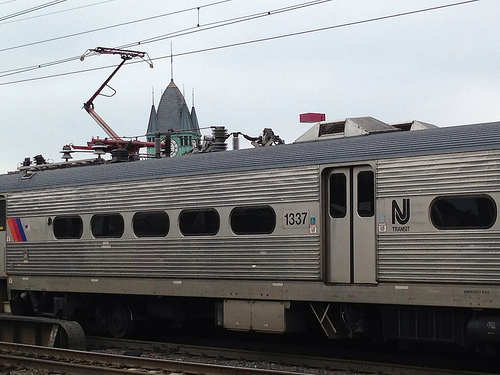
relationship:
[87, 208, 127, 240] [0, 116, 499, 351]
window on train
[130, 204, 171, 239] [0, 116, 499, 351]
window on train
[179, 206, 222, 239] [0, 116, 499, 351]
window on train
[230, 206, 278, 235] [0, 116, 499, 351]
window on train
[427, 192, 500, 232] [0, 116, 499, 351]
window on train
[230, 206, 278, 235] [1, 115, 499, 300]
window on train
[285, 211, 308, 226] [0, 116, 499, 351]
number on train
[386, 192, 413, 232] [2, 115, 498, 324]
logo on train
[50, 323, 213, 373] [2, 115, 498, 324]
track next train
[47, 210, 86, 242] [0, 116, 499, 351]
window on train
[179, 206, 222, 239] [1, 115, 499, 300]
window on train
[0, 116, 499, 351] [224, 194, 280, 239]
train has window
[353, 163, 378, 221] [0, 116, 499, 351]
window has train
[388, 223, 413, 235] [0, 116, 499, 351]
letter on train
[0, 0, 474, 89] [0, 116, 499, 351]
cables above train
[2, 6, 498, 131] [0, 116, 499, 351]
sky above train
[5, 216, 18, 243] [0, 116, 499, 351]
color on train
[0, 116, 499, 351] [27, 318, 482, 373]
train riding tracks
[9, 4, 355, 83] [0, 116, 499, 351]
cables connecting train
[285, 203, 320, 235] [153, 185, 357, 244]
number on train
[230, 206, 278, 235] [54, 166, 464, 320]
window on train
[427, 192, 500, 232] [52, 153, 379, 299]
window on train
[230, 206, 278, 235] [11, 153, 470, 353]
window on train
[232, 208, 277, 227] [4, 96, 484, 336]
window on train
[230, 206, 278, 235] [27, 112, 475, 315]
window on train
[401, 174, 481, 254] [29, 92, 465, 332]
window on train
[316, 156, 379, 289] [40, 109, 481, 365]
door on train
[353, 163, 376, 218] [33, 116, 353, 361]
window on car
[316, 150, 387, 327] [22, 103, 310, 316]
door on car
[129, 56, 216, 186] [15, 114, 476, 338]
tower behind train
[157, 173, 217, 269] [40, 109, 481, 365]
window on train